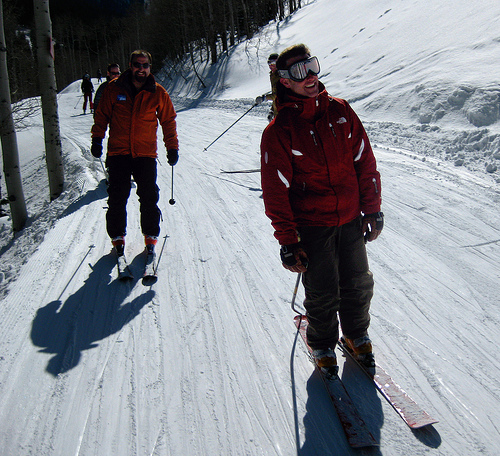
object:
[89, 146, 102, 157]
hand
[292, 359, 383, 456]
shadow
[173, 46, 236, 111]
shadow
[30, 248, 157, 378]
person shadow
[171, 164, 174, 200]
pole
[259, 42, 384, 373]
man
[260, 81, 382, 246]
red jacket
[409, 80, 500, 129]
bank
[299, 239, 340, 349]
leg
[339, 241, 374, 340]
leg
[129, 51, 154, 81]
head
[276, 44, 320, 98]
head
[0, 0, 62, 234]
trees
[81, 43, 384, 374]
group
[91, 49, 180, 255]
man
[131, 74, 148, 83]
goatee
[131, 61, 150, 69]
sunglasses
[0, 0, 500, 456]
ground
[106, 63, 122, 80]
head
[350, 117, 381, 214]
arm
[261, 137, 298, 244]
arm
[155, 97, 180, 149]
arm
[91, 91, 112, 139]
arm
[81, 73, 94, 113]
person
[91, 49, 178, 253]
men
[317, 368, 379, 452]
red ski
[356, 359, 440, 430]
red ski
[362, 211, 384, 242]
hand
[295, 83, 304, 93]
skie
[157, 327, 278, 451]
marks